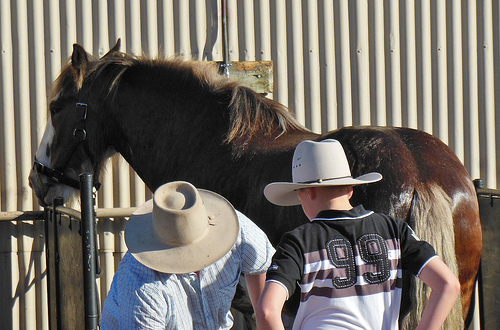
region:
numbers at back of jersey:
[316, 226, 392, 294]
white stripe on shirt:
[410, 251, 450, 275]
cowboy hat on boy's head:
[242, 133, 377, 213]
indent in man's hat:
[164, 189, 180, 203]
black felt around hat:
[296, 169, 336, 181]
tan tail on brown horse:
[403, 179, 460, 236]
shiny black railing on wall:
[204, 11, 254, 51]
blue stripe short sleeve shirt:
[160, 282, 235, 313]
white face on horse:
[22, 118, 83, 184]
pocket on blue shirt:
[211, 265, 261, 307]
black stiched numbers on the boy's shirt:
[318, 221, 400, 298]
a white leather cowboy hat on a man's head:
[123, 183, 246, 278]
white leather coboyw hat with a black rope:
[260, 133, 382, 205]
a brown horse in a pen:
[21, 53, 458, 248]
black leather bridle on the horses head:
[23, 103, 116, 194]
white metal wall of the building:
[331, 24, 474, 104]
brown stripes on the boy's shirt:
[308, 235, 405, 298]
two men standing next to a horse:
[73, 153, 463, 326]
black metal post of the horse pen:
[81, 169, 94, 329]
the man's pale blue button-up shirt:
[104, 268, 237, 328]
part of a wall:
[430, 131, 444, 153]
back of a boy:
[348, 304, 354, 311]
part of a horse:
[240, 106, 251, 113]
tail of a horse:
[437, 227, 451, 245]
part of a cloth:
[348, 265, 363, 276]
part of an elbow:
[259, 303, 264, 315]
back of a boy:
[362, 260, 371, 277]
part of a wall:
[402, 65, 427, 83]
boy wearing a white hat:
[261, 137, 392, 225]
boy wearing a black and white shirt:
[266, 218, 434, 312]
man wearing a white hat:
[111, 178, 236, 270]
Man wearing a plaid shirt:
[111, 282, 222, 328]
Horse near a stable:
[13, 122, 125, 175]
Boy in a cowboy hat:
[286, 142, 380, 202]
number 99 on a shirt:
[312, 228, 403, 291]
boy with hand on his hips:
[256, 305, 491, 328]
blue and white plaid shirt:
[143, 285, 227, 317]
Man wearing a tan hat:
[122, 195, 232, 272]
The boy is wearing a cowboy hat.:
[264, 130, 381, 217]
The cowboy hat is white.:
[261, 141, 387, 211]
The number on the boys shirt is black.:
[319, 230, 392, 297]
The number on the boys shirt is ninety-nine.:
[323, 236, 389, 292]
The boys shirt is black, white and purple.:
[267, 211, 437, 328]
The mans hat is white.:
[125, 168, 252, 271]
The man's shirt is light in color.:
[123, 281, 226, 323]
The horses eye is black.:
[51, 97, 60, 117]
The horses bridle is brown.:
[27, 151, 77, 192]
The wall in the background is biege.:
[294, 26, 386, 89]